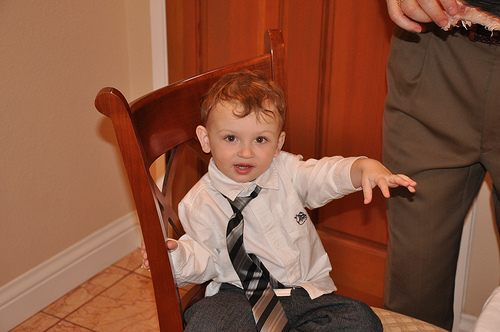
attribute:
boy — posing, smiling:
[142, 69, 420, 330]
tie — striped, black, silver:
[219, 187, 287, 331]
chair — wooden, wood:
[94, 29, 296, 329]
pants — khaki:
[384, 24, 498, 325]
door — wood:
[164, 1, 396, 307]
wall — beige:
[1, 0, 165, 328]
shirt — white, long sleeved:
[167, 151, 362, 300]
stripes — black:
[222, 194, 288, 331]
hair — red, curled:
[201, 67, 284, 132]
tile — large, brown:
[8, 240, 194, 331]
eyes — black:
[223, 134, 266, 144]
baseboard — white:
[1, 212, 147, 331]